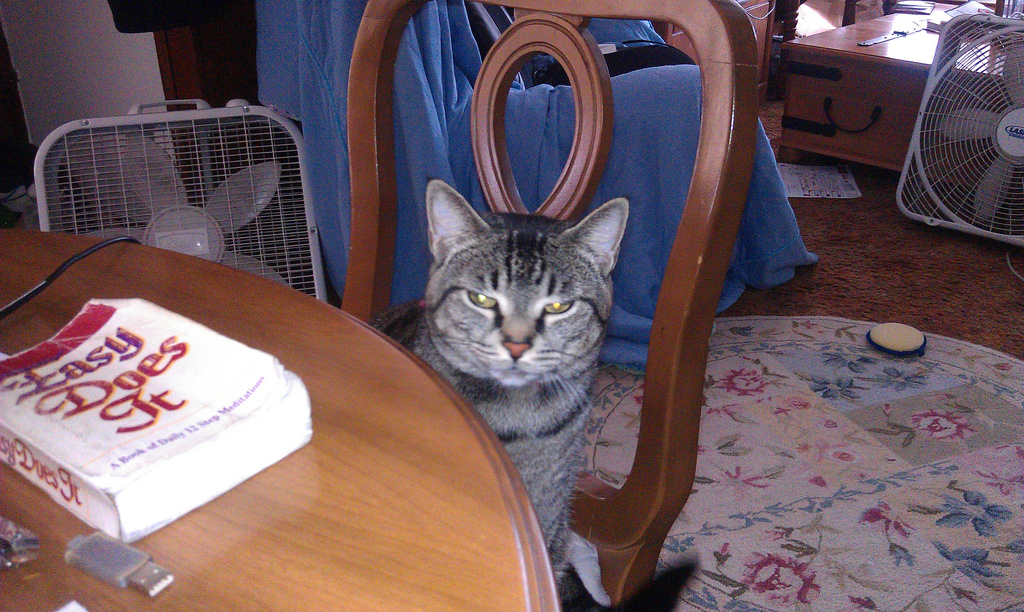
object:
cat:
[406, 178, 630, 608]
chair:
[340, 2, 761, 611]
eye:
[466, 290, 498, 310]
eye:
[540, 297, 575, 314]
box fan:
[32, 98, 330, 304]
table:
[2, 229, 561, 611]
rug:
[580, 314, 1023, 611]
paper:
[777, 161, 862, 198]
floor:
[715, 158, 1022, 360]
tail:
[559, 528, 613, 605]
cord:
[0, 233, 139, 316]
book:
[0, 297, 315, 544]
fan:
[895, 15, 1023, 249]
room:
[2, 2, 1023, 611]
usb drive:
[65, 533, 178, 597]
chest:
[778, 12, 1022, 193]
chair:
[332, 3, 756, 305]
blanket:
[254, 0, 816, 367]